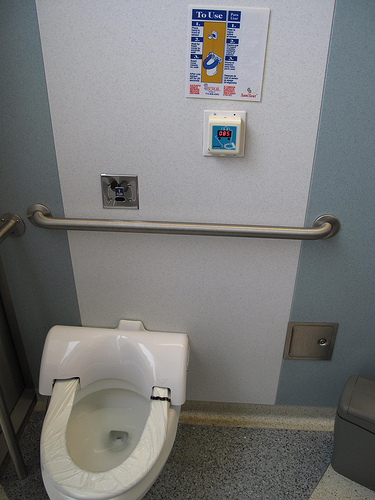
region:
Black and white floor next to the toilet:
[184, 437, 299, 493]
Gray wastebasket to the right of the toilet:
[329, 369, 370, 484]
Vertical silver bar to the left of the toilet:
[1, 415, 24, 481]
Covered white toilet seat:
[48, 386, 64, 480]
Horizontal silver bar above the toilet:
[78, 214, 284, 245]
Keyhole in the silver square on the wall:
[314, 336, 330, 351]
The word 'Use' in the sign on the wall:
[206, 8, 225, 21]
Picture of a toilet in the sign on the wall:
[201, 50, 220, 77]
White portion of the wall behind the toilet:
[68, 13, 149, 165]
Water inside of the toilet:
[87, 420, 113, 461]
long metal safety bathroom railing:
[28, 203, 341, 252]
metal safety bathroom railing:
[0, 213, 23, 246]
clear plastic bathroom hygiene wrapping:
[44, 378, 170, 498]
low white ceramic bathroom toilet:
[29, 324, 186, 499]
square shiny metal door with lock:
[276, 319, 338, 363]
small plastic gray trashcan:
[330, 375, 372, 492]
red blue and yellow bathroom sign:
[183, 5, 271, 104]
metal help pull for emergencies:
[98, 170, 143, 210]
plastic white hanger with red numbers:
[201, 109, 248, 156]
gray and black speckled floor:
[6, 400, 336, 495]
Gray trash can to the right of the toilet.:
[336, 372, 374, 489]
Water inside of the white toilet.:
[74, 392, 142, 468]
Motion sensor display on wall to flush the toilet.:
[99, 172, 139, 211]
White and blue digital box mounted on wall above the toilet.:
[210, 113, 238, 155]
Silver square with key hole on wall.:
[289, 321, 337, 362]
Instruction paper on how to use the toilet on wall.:
[190, 7, 263, 101]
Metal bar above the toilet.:
[29, 204, 340, 245]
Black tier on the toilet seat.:
[150, 389, 173, 406]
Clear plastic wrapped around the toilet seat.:
[50, 373, 159, 499]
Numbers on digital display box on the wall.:
[217, 131, 229, 139]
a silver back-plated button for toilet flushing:
[97, 170, 145, 213]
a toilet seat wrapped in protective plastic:
[34, 380, 179, 495]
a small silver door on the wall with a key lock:
[284, 313, 339, 372]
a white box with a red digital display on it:
[194, 113, 247, 159]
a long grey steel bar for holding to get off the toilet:
[27, 197, 339, 257]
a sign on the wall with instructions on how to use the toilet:
[179, 3, 273, 106]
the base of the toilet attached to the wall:
[30, 307, 194, 402]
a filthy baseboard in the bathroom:
[195, 396, 264, 438]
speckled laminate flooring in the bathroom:
[184, 438, 295, 491]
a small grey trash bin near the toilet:
[324, 373, 373, 496]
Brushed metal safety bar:
[18, 198, 360, 243]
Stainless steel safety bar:
[21, 195, 352, 257]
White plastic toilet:
[0, 294, 195, 496]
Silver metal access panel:
[274, 309, 354, 372]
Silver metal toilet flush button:
[92, 164, 154, 219]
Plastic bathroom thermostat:
[198, 97, 275, 172]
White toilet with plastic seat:
[19, 304, 214, 498]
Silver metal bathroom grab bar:
[16, 198, 356, 250]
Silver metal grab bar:
[27, 206, 352, 243]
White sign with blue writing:
[174, 2, 277, 112]